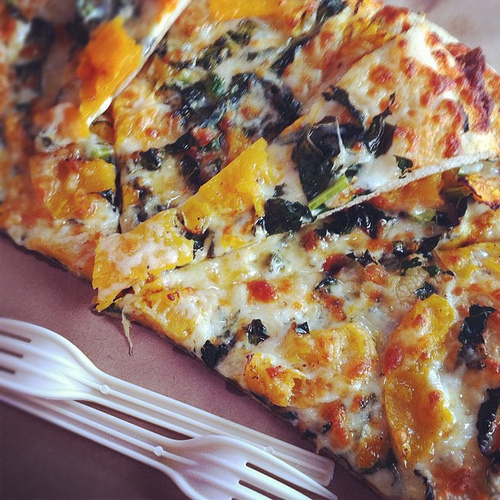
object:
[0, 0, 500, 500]
table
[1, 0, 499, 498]
lunch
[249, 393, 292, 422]
spinach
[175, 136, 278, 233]
bell pepper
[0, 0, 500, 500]
pizza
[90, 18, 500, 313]
flatbread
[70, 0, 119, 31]
spinach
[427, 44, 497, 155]
pizza crust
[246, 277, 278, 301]
sauce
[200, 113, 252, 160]
wall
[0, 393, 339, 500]
forks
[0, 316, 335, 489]
fork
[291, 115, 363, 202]
dark toppings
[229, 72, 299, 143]
dark toppings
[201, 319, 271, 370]
dark toppings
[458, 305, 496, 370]
dark toppings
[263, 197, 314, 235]
dark toppings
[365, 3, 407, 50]
pizza crust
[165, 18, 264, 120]
spinach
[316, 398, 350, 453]
tomatoes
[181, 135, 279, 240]
topping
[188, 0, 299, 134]
cheese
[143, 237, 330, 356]
cheese